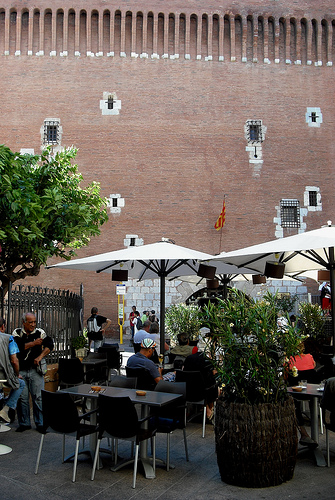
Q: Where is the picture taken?
A: A cafe.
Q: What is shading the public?
A: Umbrellas.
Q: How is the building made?
A: Of brick.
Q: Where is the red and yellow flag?
A: Against the building.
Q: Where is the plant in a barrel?
A: Next to the table.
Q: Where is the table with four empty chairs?
A: Next to the barrel.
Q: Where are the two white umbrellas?
A: Over the tables.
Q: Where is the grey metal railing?
A: Around the tree.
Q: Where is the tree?
A: Behind the metal railing.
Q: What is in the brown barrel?
A: A plant.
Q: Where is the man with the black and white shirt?
A: Next to the metal railing.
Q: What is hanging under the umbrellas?
A: Lights.